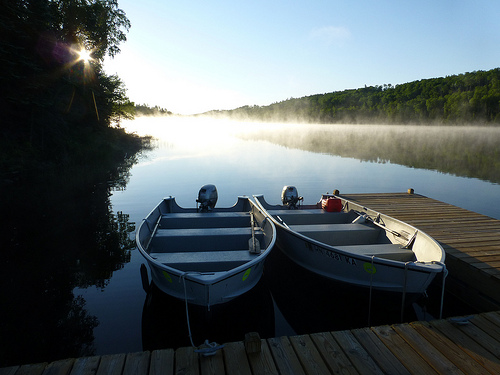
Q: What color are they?
A: White.